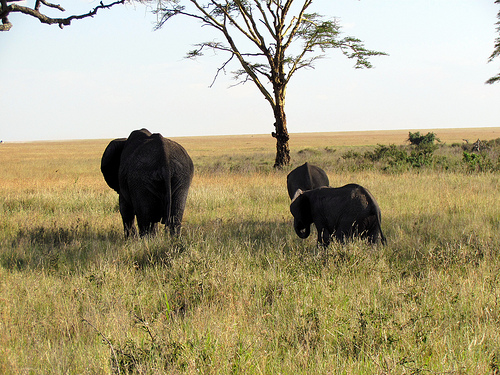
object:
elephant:
[102, 130, 191, 248]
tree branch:
[0, 0, 132, 30]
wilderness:
[0, 126, 497, 370]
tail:
[156, 135, 178, 225]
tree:
[148, 3, 386, 182]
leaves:
[354, 59, 373, 69]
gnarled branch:
[1, 0, 157, 39]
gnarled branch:
[183, 0, 223, 26]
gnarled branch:
[253, 65, 270, 82]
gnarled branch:
[296, 57, 322, 72]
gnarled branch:
[253, 2, 277, 34]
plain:
[1, 128, 499, 373]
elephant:
[283, 161, 330, 200]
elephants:
[98, 127, 391, 252]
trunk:
[289, 218, 314, 240]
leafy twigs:
[481, 0, 498, 87]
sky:
[0, 0, 498, 143]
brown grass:
[315, 134, 419, 171]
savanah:
[175, 106, 498, 323]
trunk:
[264, 106, 296, 163]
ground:
[1, 122, 497, 373]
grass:
[95, 253, 477, 370]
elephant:
[278, 186, 398, 255]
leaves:
[301, 12, 363, 64]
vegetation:
[340, 126, 498, 176]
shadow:
[29, 237, 198, 312]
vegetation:
[407, 128, 441, 151]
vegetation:
[460, 140, 490, 169]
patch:
[187, 140, 498, 181]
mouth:
[306, 216, 313, 226]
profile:
[286, 181, 385, 241]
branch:
[40, 1, 115, 37]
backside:
[285, 162, 325, 192]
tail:
[300, 157, 313, 194]